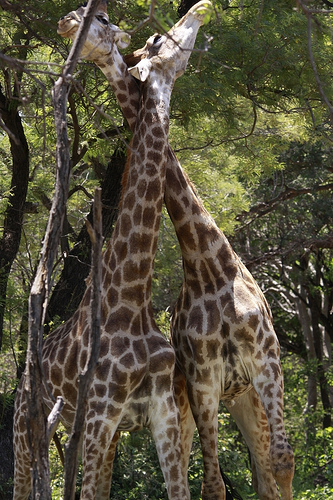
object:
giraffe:
[45, 1, 217, 499]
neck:
[98, 82, 174, 322]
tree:
[171, 3, 332, 162]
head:
[126, 1, 213, 79]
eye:
[153, 31, 164, 45]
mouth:
[178, 1, 215, 33]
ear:
[128, 59, 154, 81]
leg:
[250, 360, 295, 500]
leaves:
[183, 10, 310, 120]